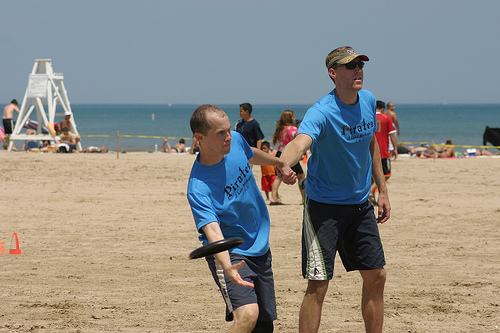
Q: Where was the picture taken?
A: On a beach.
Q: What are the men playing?
A: Frisbee.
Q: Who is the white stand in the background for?
A: Lifeguard.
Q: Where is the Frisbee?
A: In the air.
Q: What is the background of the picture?
A: The ocean.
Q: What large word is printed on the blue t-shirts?
A: Pirates.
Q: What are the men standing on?
A: Sand.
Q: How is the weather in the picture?
A: Sunny.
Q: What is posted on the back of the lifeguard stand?
A: Rules.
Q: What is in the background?
A: Ocean.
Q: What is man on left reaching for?
A: Frisbee.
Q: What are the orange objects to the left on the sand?
A: Cones.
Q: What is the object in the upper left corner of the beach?
A: Lifeguard chair.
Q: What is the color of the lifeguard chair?
A: White.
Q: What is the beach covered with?
A: Sand.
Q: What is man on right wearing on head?
A: Cap.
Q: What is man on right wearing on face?
A: Sunglasses.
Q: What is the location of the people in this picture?
A: The beach.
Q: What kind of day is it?
A: Sunny.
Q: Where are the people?
A: Beach.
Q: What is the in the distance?
A: Ocean.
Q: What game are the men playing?
A: Frisbee.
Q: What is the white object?
A: Chair.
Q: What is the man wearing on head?
A: Visor.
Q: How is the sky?
A: Hazy.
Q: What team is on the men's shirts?
A: Pirates.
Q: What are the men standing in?
A: Sand.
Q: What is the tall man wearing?
A: Sunglasses.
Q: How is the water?
A: Blue.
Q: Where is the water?
A: Background.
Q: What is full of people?
A: Beach.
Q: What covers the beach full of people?
A: Sand.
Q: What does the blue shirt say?
A: Pirates.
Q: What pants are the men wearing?
A: Shorts.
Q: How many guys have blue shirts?
A: 2.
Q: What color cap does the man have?
A: Green.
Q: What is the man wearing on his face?
A: Sunglasses.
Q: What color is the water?
A: Blue.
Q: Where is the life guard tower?
A: In the back left corner of the picture.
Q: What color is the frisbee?
A: Black.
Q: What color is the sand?
A: Brown.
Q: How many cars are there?
A: None.